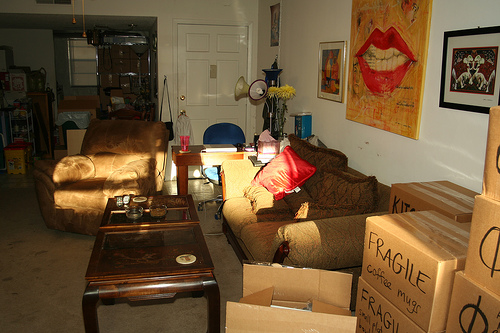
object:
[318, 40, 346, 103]
art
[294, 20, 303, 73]
wall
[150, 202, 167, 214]
ashtray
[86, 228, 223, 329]
table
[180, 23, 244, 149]
door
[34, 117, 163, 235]
chair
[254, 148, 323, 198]
pillow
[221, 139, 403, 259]
couch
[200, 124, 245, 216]
chair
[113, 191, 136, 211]
remotes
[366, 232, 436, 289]
fragile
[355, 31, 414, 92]
lips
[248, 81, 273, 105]
lamp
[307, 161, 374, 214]
pillows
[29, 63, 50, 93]
vase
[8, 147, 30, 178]
pile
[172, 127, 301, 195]
desk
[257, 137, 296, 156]
tissues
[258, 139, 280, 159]
box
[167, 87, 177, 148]
purse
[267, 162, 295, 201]
sunlight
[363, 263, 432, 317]
coffee mugs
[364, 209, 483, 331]
box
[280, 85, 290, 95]
flowers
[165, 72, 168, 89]
hook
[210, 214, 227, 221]
wheels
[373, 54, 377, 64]
teeth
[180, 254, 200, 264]
coaster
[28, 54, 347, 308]
room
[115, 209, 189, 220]
glass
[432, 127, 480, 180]
wall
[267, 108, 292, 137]
vase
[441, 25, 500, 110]
art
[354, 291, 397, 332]
fragile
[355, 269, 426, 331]
box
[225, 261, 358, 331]
box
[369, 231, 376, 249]
black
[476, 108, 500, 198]
boxes